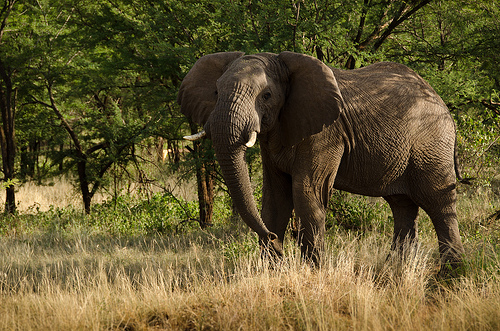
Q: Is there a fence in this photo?
A: No, there are no fences.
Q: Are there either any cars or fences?
A: No, there are no fences or cars.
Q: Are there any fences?
A: No, there are no fences.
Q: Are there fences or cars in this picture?
A: No, there are no fences or cars.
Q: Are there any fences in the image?
A: No, there are no fences.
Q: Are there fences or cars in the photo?
A: No, there are no fences or cars.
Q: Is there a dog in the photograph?
A: No, there are no dogs.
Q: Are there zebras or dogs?
A: No, there are no dogs or zebras.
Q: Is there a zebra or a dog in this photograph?
A: No, there are no dogs or zebras.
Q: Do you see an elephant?
A: Yes, there is an elephant.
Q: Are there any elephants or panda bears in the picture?
A: Yes, there is an elephant.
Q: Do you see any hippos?
A: No, there are no hippos.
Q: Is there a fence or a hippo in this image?
A: No, there are no hippos or fences.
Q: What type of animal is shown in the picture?
A: The animal is an elephant.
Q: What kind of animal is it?
A: The animal is an elephant.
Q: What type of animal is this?
A: This is an elephant.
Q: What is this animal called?
A: This is an elephant.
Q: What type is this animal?
A: This is an elephant.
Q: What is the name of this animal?
A: This is an elephant.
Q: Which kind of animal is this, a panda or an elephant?
A: This is an elephant.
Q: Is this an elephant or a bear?
A: This is an elephant.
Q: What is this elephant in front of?
A: The elephant is in front of the tree.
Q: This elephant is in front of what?
A: The elephant is in front of the tree.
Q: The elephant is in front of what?
A: The elephant is in front of the tree.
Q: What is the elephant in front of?
A: The elephant is in front of the tree.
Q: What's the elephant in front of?
A: The elephant is in front of the tree.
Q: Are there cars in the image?
A: No, there are no cars.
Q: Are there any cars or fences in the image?
A: No, there are no cars or fences.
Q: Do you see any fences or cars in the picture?
A: No, there are no cars or fences.